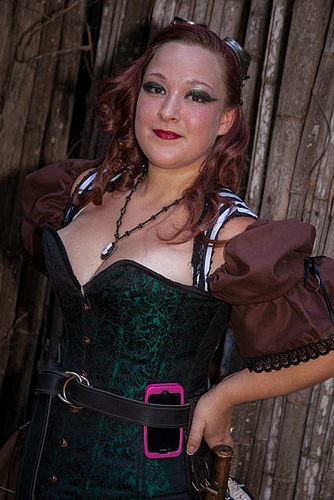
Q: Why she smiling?
A: Posing for camera.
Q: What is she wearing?
A: Renaissance outfit.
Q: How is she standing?
A: Hand on her hip.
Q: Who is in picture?
A: Woman.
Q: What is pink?
A: Her phone.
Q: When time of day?
A: Daytime.